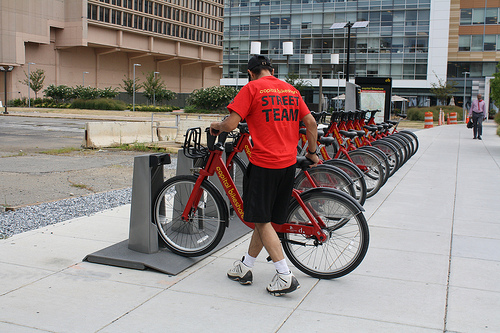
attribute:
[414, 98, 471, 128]
traffic cones — orange, white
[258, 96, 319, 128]
street — black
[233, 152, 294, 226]
shorts — black, mans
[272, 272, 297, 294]
shoes — white, tennis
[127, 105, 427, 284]
bikes — row, red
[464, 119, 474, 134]
bag — black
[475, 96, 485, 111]
tie — red